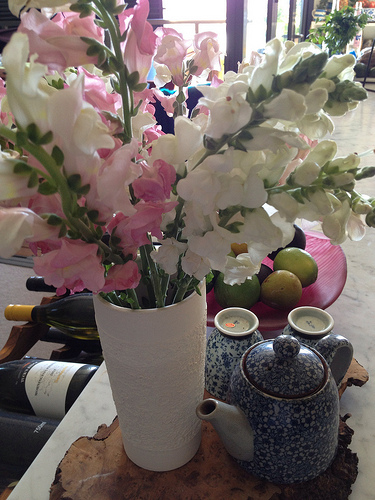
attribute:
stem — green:
[85, 5, 170, 305]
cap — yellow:
[1, 300, 35, 323]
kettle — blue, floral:
[196, 331, 354, 483]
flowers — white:
[0, 0, 372, 308]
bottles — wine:
[1, 294, 102, 471]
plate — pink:
[202, 228, 345, 330]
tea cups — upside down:
[204, 305, 330, 399]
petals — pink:
[128, 172, 167, 202]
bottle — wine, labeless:
[5, 295, 103, 340]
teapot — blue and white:
[198, 332, 352, 484]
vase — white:
[93, 273, 206, 470]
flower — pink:
[24, 237, 105, 297]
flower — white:
[178, 151, 264, 237]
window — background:
[154, 10, 290, 91]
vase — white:
[73, 290, 220, 491]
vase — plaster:
[80, 278, 247, 487]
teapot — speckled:
[229, 334, 366, 492]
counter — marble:
[329, 237, 371, 381]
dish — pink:
[286, 218, 364, 315]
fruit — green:
[211, 265, 319, 313]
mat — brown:
[80, 432, 257, 491]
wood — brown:
[60, 388, 340, 492]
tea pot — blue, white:
[206, 330, 328, 465]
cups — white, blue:
[207, 296, 365, 379]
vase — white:
[77, 278, 225, 424]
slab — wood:
[73, 408, 276, 488]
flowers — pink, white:
[27, 35, 255, 251]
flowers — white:
[39, 63, 284, 253]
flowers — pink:
[31, 49, 198, 252]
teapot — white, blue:
[241, 330, 324, 420]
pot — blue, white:
[208, 311, 374, 441]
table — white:
[42, 358, 97, 458]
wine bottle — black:
[2, 327, 121, 433]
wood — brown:
[24, 421, 165, 497]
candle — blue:
[282, 294, 351, 356]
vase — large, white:
[61, 241, 219, 472]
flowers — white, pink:
[2, 38, 351, 305]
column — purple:
[213, 4, 248, 69]